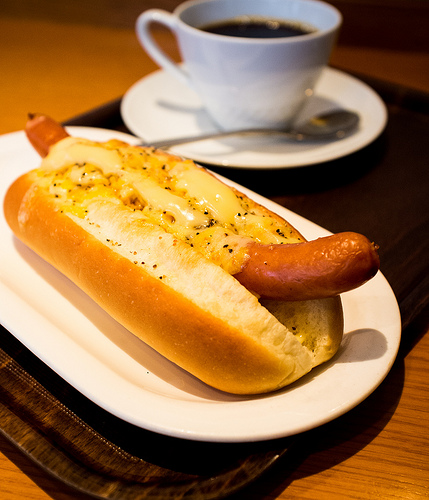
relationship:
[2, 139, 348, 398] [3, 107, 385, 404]
roll for hot dog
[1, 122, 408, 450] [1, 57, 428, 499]
plate on place mat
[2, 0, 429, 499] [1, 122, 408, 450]
table under plate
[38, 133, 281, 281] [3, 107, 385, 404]
cheese on hot dog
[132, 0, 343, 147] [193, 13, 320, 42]
cup filled with coffee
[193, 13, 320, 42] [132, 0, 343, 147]
coffee in cup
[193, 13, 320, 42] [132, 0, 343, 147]
coffee on cup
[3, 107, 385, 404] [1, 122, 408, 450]
hot dog on plate